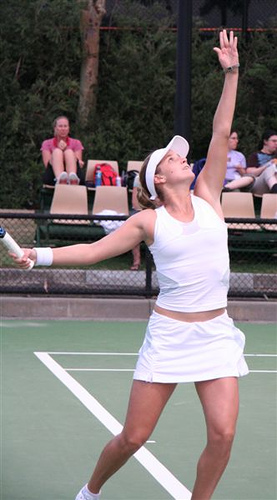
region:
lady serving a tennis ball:
[7, 14, 255, 429]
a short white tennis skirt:
[111, 286, 256, 441]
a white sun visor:
[107, 119, 207, 217]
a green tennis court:
[27, 310, 208, 480]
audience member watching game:
[26, 93, 96, 199]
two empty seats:
[50, 180, 127, 226]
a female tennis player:
[0, 27, 249, 496]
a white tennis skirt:
[129, 308, 246, 378]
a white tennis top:
[143, 191, 225, 306]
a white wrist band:
[31, 244, 48, 262]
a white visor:
[145, 133, 184, 196]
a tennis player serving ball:
[0, 27, 249, 496]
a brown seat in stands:
[51, 185, 88, 224]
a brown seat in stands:
[93, 183, 129, 225]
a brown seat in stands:
[221, 189, 259, 230]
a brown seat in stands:
[259, 191, 276, 229]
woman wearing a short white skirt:
[132, 309, 250, 378]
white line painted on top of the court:
[34, 351, 193, 498]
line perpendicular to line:
[48, 351, 139, 355]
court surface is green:
[0, 318, 276, 498]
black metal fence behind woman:
[0, 212, 276, 300]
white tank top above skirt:
[146, 193, 233, 310]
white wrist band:
[33, 247, 53, 266]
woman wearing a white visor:
[144, 134, 187, 198]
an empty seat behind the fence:
[48, 184, 87, 223]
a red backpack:
[93, 163, 117, 185]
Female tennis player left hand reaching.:
[131, 23, 246, 313]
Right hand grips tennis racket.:
[2, 215, 36, 283]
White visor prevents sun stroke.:
[129, 126, 199, 207]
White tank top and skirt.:
[143, 196, 250, 403]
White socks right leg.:
[71, 477, 110, 499]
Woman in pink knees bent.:
[45, 112, 84, 184]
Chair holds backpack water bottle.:
[87, 156, 124, 191]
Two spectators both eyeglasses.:
[229, 127, 276, 196]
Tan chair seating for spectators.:
[46, 181, 135, 240]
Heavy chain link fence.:
[218, 217, 276, 301]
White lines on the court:
[24, 344, 269, 494]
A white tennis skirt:
[125, 303, 251, 383]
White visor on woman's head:
[130, 125, 195, 210]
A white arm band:
[24, 238, 54, 268]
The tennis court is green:
[0, 313, 272, 494]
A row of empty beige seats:
[43, 177, 271, 232]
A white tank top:
[140, 192, 233, 313]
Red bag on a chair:
[77, 152, 124, 188]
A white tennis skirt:
[127, 305, 254, 389]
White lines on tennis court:
[29, 342, 271, 494]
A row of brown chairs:
[43, 176, 271, 236]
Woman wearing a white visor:
[133, 130, 196, 209]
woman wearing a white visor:
[133, 118, 241, 320]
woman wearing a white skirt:
[129, 135, 249, 381]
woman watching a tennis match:
[34, 111, 95, 213]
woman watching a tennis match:
[217, 123, 258, 196]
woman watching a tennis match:
[248, 128, 275, 190]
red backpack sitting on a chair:
[87, 147, 126, 195]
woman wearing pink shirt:
[34, 114, 89, 182]